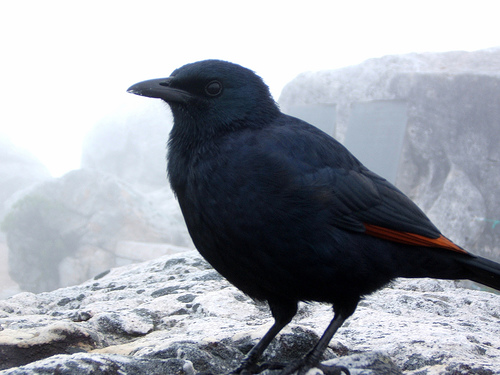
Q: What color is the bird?
A: The bird is black.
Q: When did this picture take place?
A: It took place in the day time.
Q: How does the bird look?
A: The bird looks mean.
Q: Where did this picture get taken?
A: It was taken in the mountains.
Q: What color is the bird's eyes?
A: The birds eyes are black.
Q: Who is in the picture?
A: Nobody is in the picture.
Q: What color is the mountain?
A: The mountain is grey.